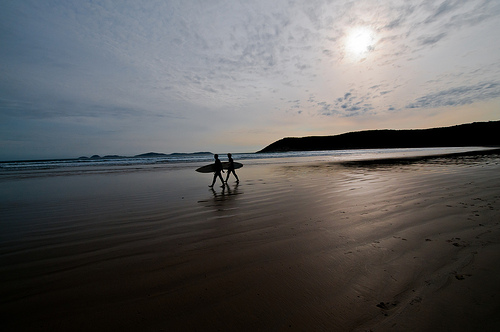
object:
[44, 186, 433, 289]
sand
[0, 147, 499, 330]
beach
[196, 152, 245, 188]
people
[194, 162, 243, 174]
surfboard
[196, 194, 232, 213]
footprints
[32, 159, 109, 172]
waves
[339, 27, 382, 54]
sun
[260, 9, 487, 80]
clouds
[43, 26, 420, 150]
sky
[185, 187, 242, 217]
shadow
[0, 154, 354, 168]
ocean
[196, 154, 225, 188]
man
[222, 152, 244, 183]
woman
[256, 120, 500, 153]
hills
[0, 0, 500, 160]
background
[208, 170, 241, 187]
legs